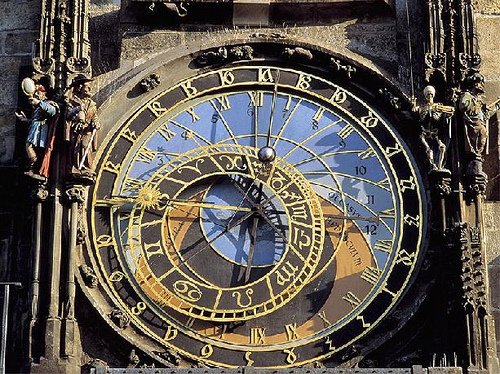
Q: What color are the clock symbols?
A: Yellow.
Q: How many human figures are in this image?
A: Four.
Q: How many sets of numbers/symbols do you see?
A: Four.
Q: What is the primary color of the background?
A: Brown.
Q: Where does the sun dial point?
A: Left.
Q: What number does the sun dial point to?
A: Eleven.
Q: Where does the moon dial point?
A: Up.